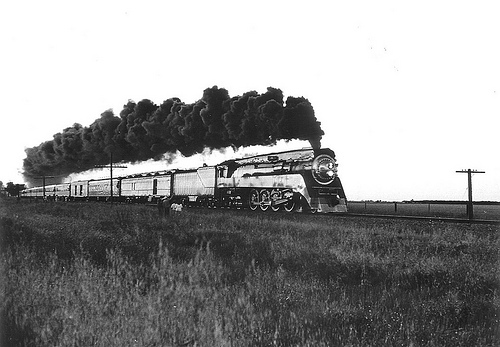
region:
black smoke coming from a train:
[20, 80, 330, 185]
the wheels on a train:
[242, 185, 299, 211]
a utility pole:
[449, 162, 488, 226]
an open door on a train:
[146, 176, 159, 196]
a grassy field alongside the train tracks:
[0, 224, 493, 338]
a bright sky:
[0, 0, 499, 194]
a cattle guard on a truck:
[308, 192, 350, 218]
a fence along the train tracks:
[348, 196, 499, 217]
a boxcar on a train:
[69, 177, 89, 199]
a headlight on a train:
[327, 169, 335, 176]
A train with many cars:
[15, 145, 367, 230]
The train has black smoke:
[35, 97, 324, 173]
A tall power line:
[455, 160, 482, 217]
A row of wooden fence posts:
[337, 184, 478, 222]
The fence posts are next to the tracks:
[336, 189, 464, 219]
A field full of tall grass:
[8, 196, 463, 334]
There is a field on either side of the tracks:
[14, 194, 491, 333]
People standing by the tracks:
[151, 189, 188, 219]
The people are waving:
[155, 191, 175, 217]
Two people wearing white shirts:
[169, 197, 191, 219]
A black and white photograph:
[0, 0, 499, 342]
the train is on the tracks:
[23, 144, 386, 223]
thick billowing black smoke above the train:
[19, 86, 342, 151]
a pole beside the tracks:
[446, 162, 488, 217]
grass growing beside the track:
[66, 245, 291, 332]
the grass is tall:
[35, 250, 270, 335]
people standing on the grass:
[146, 182, 191, 227]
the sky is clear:
[138, 0, 438, 67]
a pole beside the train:
[94, 150, 129, 208]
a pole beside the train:
[27, 165, 62, 205]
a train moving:
[8, 130, 362, 222]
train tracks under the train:
[96, 201, 494, 220]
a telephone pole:
[434, 153, 495, 225]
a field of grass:
[43, 221, 260, 297]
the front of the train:
[287, 132, 369, 225]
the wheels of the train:
[209, 177, 312, 217]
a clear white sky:
[275, 0, 427, 111]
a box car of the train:
[93, 155, 198, 221]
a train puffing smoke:
[0, 53, 395, 258]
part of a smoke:
[253, 109, 273, 115]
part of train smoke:
[186, 107, 203, 138]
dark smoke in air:
[177, 119, 190, 137]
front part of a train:
[315, 167, 347, 199]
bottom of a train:
[261, 197, 278, 198]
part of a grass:
[267, 272, 287, 306]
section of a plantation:
[128, 273, 155, 324]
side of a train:
[209, 176, 219, 178]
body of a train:
[51, 167, 55, 199]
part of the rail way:
[411, 206, 433, 218]